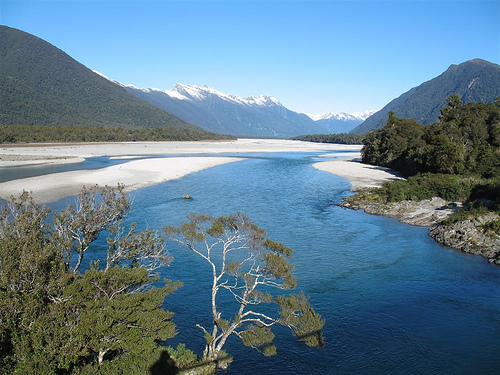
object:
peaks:
[92, 67, 376, 140]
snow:
[158, 80, 218, 105]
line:
[314, 145, 500, 269]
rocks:
[486, 258, 496, 264]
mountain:
[0, 22, 500, 143]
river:
[0, 137, 500, 375]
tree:
[359, 92, 500, 171]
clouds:
[0, 0, 499, 84]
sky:
[0, 0, 499, 112]